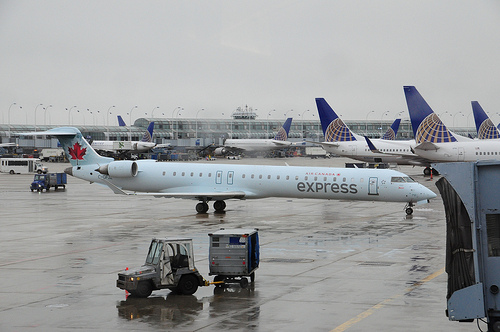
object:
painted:
[305, 261, 450, 331]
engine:
[93, 155, 148, 181]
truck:
[114, 228, 262, 298]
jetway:
[0, 157, 482, 331]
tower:
[227, 104, 259, 120]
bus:
[0, 157, 48, 174]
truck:
[29, 167, 71, 196]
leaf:
[59, 140, 89, 166]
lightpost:
[6, 102, 29, 129]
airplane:
[8, 122, 438, 218]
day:
[1, 1, 471, 216]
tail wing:
[7, 125, 117, 166]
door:
[214, 169, 223, 185]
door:
[225, 170, 233, 183]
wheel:
[194, 200, 210, 213]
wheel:
[211, 199, 227, 213]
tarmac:
[1, 153, 484, 330]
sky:
[1, 0, 483, 127]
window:
[161, 170, 165, 175]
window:
[171, 170, 177, 177]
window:
[188, 170, 195, 177]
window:
[240, 172, 246, 180]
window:
[284, 173, 291, 180]